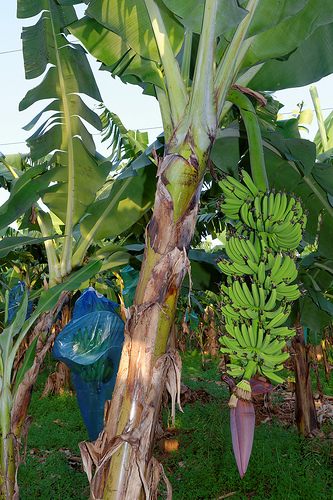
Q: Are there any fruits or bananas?
A: Yes, there is a banana.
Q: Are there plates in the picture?
A: No, there are no plates.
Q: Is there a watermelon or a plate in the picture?
A: No, there are no plates or watermelons.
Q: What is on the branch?
A: The banana is on the branch.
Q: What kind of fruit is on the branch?
A: The fruit is a banana.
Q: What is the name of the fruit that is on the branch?
A: The fruit is a banana.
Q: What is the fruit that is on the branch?
A: The fruit is a banana.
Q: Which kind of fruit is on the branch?
A: The fruit is a banana.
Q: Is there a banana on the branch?
A: Yes, there is a banana on the branch.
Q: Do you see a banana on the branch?
A: Yes, there is a banana on the branch.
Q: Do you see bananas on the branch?
A: Yes, there is a banana on the branch.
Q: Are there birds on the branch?
A: No, there is a banana on the branch.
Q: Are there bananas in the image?
A: Yes, there is a banana.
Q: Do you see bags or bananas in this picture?
A: Yes, there is a banana.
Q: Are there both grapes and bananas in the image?
A: No, there is a banana but no grapes.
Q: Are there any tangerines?
A: No, there are no tangerines.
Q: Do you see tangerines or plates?
A: No, there are no tangerines or plates.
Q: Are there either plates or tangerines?
A: No, there are no tangerines or plates.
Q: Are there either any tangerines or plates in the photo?
A: No, there are no tangerines or plates.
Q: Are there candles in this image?
A: No, there are no candles.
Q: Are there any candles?
A: No, there are no candles.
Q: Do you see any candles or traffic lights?
A: No, there are no candles or traffic lights.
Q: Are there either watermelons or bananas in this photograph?
A: Yes, there is a banana.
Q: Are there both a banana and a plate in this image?
A: No, there is a banana but no plates.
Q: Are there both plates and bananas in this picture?
A: No, there is a banana but no plates.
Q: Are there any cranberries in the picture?
A: No, there are no cranberries.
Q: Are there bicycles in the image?
A: No, there are no bicycles.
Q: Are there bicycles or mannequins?
A: No, there are no bicycles or mannequins.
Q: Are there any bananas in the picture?
A: Yes, there is a banana.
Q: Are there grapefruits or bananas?
A: Yes, there is a banana.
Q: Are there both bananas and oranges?
A: No, there is a banana but no oranges.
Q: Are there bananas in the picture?
A: Yes, there is a banana.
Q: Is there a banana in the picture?
A: Yes, there is a banana.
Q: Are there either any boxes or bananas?
A: Yes, there is a banana.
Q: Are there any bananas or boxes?
A: Yes, there is a banana.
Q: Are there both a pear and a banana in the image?
A: No, there is a banana but no pears.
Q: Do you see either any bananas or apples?
A: Yes, there are bananas.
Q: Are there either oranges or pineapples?
A: No, there are no oranges or pineapples.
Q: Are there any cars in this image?
A: No, there are no cars.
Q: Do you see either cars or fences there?
A: No, there are no cars or fences.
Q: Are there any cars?
A: No, there are no cars.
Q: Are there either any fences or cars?
A: No, there are no cars or fences.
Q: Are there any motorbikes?
A: No, there are no motorbikes.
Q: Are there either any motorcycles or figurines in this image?
A: No, there are no motorcycles or figurines.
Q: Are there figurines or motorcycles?
A: No, there are no motorcycles or figurines.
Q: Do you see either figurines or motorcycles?
A: No, there are no motorcycles or figurines.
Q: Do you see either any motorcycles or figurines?
A: No, there are no motorcycles or figurines.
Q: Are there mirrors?
A: No, there are no mirrors.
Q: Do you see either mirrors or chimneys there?
A: No, there are no mirrors or chimneys.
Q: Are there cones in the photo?
A: No, there are no cones.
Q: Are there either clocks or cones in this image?
A: No, there are no cones or clocks.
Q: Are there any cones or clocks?
A: No, there are no cones or clocks.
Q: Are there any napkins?
A: No, there are no napkins.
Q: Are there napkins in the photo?
A: No, there are no napkins.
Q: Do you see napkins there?
A: No, there are no napkins.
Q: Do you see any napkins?
A: No, there are no napkins.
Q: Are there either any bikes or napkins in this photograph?
A: No, there are no napkins or bikes.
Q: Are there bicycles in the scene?
A: No, there are no bicycles.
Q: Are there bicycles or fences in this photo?
A: No, there are no bicycles or fences.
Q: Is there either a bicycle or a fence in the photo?
A: No, there are no bicycles or fences.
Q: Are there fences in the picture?
A: No, there are no fences.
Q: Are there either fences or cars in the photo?
A: No, there are no fences or cars.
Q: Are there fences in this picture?
A: No, there are no fences.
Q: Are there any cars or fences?
A: No, there are no fences or cars.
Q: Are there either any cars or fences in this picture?
A: No, there are no cars or fences.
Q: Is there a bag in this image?
A: Yes, there is a bag.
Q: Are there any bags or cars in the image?
A: Yes, there is a bag.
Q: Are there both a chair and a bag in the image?
A: No, there is a bag but no chairs.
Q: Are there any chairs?
A: No, there are no chairs.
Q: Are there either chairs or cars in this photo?
A: No, there are no chairs or cars.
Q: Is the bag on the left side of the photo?
A: Yes, the bag is on the left of the image.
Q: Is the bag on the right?
A: No, the bag is on the left of the image.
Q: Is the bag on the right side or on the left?
A: The bag is on the left of the image.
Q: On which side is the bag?
A: The bag is on the left of the image.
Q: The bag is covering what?
A: The bag is covering the bananas.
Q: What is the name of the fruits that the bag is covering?
A: The fruits are bananas.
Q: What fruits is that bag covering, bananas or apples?
A: The bag is covering bananas.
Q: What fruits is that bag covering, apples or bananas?
A: The bag is covering bananas.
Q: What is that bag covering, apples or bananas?
A: The bag is covering bananas.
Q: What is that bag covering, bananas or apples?
A: The bag is covering bananas.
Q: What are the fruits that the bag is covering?
A: The fruits are bananas.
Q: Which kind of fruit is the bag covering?
A: The bag is covering the bananas.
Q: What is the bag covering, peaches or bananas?
A: The bag is covering bananas.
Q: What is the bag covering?
A: The bag is covering the bananas.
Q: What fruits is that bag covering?
A: The bag is covering the bananas.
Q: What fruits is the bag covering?
A: The bag is covering the bananas.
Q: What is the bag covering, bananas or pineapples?
A: The bag is covering bananas.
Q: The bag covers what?
A: The bag covers the bananas.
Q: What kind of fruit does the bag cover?
A: The bag covers the bananas.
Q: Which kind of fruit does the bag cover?
A: The bag covers the bananas.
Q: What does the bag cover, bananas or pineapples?
A: The bag covers bananas.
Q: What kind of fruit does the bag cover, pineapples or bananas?
A: The bag covers bananas.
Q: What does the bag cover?
A: The bag covers the bananas.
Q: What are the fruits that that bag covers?
A: The fruits are bananas.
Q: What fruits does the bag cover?
A: The bag covers the bananas.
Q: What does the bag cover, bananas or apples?
A: The bag covers bananas.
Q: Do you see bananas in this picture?
A: Yes, there is a banana.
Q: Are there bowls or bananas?
A: Yes, there is a banana.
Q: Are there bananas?
A: Yes, there is a banana.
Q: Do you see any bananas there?
A: Yes, there is a banana.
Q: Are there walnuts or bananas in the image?
A: Yes, there is a banana.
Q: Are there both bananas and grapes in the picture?
A: No, there is a banana but no grapes.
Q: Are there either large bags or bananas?
A: Yes, there is a large banana.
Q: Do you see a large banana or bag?
A: Yes, there is a large banana.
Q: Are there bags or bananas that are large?
A: Yes, the banana is large.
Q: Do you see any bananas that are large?
A: Yes, there is a large banana.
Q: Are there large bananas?
A: Yes, there is a large banana.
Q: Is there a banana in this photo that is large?
A: Yes, there is a banana that is large.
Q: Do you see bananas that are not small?
A: Yes, there is a large banana.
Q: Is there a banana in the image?
A: Yes, there are bananas.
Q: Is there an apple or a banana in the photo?
A: Yes, there are bananas.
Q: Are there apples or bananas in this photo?
A: Yes, there are bananas.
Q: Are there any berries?
A: No, there are no berries.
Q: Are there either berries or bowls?
A: No, there are no berries or bowls.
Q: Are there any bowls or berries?
A: No, there are no berries or bowls.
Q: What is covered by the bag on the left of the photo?
A: The bananas are covered by the bag.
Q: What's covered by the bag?
A: The bananas are covered by the bag.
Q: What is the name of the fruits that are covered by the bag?
A: The fruits are bananas.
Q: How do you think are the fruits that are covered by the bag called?
A: The fruits are bananas.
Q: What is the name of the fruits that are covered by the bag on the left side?
A: The fruits are bananas.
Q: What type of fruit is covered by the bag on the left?
A: The fruits are bananas.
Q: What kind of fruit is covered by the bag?
A: The fruits are bananas.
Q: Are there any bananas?
A: Yes, there are bananas.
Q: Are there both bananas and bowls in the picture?
A: No, there are bananas but no bowls.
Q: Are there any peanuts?
A: No, there are no peanuts.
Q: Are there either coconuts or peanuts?
A: No, there are no peanuts or coconuts.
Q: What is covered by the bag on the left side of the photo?
A: The bananas are covered by the bag.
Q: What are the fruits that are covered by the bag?
A: The fruits are bananas.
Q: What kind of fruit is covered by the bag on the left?
A: The fruits are bananas.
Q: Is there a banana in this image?
A: Yes, there are bananas.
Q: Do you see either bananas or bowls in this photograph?
A: Yes, there are bananas.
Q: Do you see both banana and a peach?
A: No, there are bananas but no peaches.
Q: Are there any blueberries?
A: No, there are no blueberries.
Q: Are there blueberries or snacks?
A: No, there are no blueberries or snacks.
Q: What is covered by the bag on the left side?
A: The bananas are covered by the bag.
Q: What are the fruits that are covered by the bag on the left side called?
A: The fruits are bananas.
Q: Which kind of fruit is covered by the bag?
A: The fruits are bananas.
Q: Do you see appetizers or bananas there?
A: Yes, there are bananas.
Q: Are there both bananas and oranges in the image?
A: No, there are bananas but no oranges.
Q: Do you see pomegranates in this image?
A: No, there are no pomegranates.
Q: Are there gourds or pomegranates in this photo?
A: No, there are no pomegranates or gourds.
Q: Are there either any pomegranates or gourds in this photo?
A: No, there are no pomegranates or gourds.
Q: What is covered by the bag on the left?
A: The bananas are covered by the bag.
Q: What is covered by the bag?
A: The bananas are covered by the bag.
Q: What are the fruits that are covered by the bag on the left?
A: The fruits are bananas.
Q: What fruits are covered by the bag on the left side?
A: The fruits are bananas.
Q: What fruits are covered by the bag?
A: The fruits are bananas.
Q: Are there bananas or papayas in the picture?
A: Yes, there is a banana.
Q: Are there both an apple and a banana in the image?
A: No, there is a banana but no apples.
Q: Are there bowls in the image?
A: No, there are no bowls.